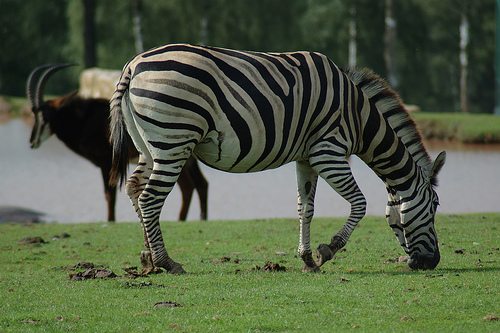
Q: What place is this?
A: It is a lake.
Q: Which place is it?
A: It is a lake.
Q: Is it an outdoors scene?
A: Yes, it is outdoors.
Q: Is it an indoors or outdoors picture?
A: It is outdoors.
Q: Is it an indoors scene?
A: No, it is outdoors.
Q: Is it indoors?
A: No, it is outdoors.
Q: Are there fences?
A: No, there are no fences.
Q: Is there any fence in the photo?
A: No, there are no fences.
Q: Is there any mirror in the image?
A: No, there are no mirrors.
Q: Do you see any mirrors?
A: No, there are no mirrors.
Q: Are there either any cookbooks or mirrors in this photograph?
A: No, there are no mirrors or cookbooks.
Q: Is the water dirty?
A: Yes, the water is dirty.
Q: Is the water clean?
A: No, the water is dirty.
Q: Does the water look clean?
A: No, the water is dirty.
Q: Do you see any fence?
A: No, there are no fences.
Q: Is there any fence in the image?
A: No, there are no fences.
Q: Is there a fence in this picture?
A: No, there are no fences.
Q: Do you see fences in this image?
A: No, there are no fences.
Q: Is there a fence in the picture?
A: No, there are no fences.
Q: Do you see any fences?
A: No, there are no fences.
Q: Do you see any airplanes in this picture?
A: No, there are no airplanes.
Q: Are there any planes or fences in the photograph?
A: No, there are no planes or fences.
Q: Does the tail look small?
A: Yes, the tail is small.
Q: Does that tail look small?
A: Yes, the tail is small.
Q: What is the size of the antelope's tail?
A: The tail is small.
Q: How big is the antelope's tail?
A: The tail is small.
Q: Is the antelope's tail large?
A: No, the tail is small.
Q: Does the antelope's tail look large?
A: No, the tail is small.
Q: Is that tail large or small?
A: The tail is small.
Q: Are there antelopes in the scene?
A: Yes, there is an antelope.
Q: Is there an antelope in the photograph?
A: Yes, there is an antelope.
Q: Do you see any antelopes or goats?
A: Yes, there is an antelope.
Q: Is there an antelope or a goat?
A: Yes, there is an antelope.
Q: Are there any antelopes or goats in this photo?
A: Yes, there is an antelope.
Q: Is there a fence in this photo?
A: No, there are no fences.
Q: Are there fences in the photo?
A: No, there are no fences.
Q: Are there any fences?
A: No, there are no fences.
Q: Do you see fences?
A: No, there are no fences.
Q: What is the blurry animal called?
A: The animal is an antelope.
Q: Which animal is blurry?
A: The animal is an antelope.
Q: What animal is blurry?
A: The animal is an antelope.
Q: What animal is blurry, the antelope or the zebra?
A: The antelope is blurry.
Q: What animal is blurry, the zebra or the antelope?
A: The antelope is blurry.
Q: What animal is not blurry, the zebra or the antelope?
A: The zebra is not blurry.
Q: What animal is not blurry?
A: The animal is a zebra.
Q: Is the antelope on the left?
A: Yes, the antelope is on the left of the image.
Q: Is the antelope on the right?
A: No, the antelope is on the left of the image.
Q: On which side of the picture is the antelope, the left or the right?
A: The antelope is on the left of the image.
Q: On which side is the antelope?
A: The antelope is on the left of the image.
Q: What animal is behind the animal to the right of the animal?
A: The animal is an antelope.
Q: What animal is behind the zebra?
A: The animal is an antelope.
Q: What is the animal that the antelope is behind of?
A: The animal is a zebra.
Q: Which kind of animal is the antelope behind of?
A: The antelope is behind the zebra.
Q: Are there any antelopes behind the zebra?
A: Yes, there is an antelope behind the zebra.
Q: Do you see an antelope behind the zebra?
A: Yes, there is an antelope behind the zebra.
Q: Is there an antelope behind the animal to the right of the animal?
A: Yes, there is an antelope behind the zebra.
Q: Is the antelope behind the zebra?
A: Yes, the antelope is behind the zebra.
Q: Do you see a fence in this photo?
A: No, there are no fences.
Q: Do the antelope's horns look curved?
A: Yes, the horns are curved.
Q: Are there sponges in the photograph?
A: No, there are no sponges.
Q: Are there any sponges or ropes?
A: No, there are no sponges or ropes.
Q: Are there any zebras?
A: Yes, there is a zebra.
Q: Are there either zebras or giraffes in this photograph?
A: Yes, there is a zebra.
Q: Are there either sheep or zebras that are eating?
A: Yes, the zebra is eating.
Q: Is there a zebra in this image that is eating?
A: Yes, there is a zebra that is eating.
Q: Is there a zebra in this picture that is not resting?
A: Yes, there is a zebra that is eating.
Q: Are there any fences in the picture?
A: No, there are no fences.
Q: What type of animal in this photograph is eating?
A: The animal is a zebra.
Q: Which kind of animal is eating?
A: The animal is a zebra.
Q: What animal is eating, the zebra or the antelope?
A: The zebra is eating.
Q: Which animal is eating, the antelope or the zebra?
A: The zebra is eating.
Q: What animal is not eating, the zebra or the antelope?
A: The antelope is not eating.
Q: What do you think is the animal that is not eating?
A: The animal is an antelope.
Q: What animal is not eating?
A: The animal is an antelope.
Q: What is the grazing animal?
A: The animal is a zebra.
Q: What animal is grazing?
A: The animal is a zebra.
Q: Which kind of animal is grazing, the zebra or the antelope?
A: The zebra is grazing.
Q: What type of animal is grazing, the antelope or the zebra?
A: The zebra is grazing.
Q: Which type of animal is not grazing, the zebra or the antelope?
A: The antelope is not grazing.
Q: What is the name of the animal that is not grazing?
A: The animal is an antelope.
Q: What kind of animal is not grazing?
A: The animal is an antelope.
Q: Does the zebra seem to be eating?
A: Yes, the zebra is eating.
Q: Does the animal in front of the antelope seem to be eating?
A: Yes, the zebra is eating.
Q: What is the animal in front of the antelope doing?
A: The zebra is eating.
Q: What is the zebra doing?
A: The zebra is eating.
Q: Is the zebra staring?
A: No, the zebra is eating.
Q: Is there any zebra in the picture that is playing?
A: No, there is a zebra but it is eating.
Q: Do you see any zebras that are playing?
A: No, there is a zebra but it is eating.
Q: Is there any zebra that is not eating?
A: No, there is a zebra but it is eating.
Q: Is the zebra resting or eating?
A: The zebra is eating.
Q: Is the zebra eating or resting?
A: The zebra is eating.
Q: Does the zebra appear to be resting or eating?
A: The zebra is eating.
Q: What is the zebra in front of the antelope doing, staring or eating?
A: The zebra is eating.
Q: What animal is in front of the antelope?
A: The zebra is in front of the antelope.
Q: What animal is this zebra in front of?
A: The zebra is in front of the antelope.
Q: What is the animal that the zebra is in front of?
A: The animal is an antelope.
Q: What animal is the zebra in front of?
A: The zebra is in front of the antelope.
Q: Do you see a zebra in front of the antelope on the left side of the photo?
A: Yes, there is a zebra in front of the antelope.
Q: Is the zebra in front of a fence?
A: No, the zebra is in front of the antelope.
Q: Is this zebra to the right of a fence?
A: No, the zebra is to the right of an animal.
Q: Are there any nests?
A: No, there are no nests.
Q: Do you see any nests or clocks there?
A: No, there are no nests or clocks.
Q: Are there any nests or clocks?
A: No, there are no nests or clocks.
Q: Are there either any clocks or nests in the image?
A: No, there are no nests or clocks.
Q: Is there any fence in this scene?
A: No, there are no fences.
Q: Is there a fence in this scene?
A: No, there are no fences.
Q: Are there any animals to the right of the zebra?
A: No, the animal is to the left of the zebra.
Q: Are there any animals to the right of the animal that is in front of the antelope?
A: No, the animal is to the left of the zebra.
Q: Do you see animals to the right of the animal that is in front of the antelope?
A: No, the animal is to the left of the zebra.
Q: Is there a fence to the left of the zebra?
A: No, there is an animal to the left of the zebra.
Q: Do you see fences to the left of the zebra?
A: No, there is an animal to the left of the zebra.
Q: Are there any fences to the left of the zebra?
A: No, there is an animal to the left of the zebra.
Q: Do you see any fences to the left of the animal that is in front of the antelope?
A: No, there is an animal to the left of the zebra.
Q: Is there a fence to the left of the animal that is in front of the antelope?
A: No, there is an animal to the left of the zebra.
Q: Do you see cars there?
A: No, there are no cars.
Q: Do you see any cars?
A: No, there are no cars.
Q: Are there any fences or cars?
A: No, there are no cars or fences.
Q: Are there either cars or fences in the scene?
A: No, there are no cars or fences.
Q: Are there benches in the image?
A: No, there are no benches.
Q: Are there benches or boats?
A: No, there are no benches or boats.